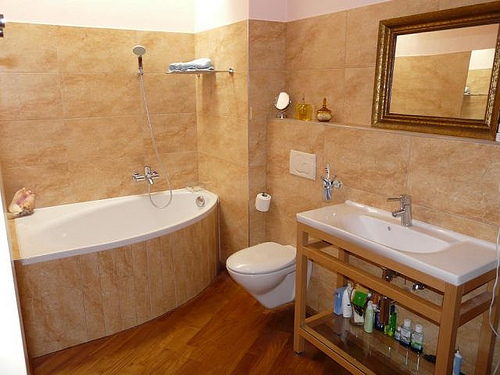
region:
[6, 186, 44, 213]
Shell on side of bathtub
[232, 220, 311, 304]
European style toilet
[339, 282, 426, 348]
Soaps and shampoos under sink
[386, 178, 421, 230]
Sink nossel is silver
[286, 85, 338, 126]
Oil in corner of bathroom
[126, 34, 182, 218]
Shower head over bath tub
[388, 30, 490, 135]
Mirror of bathroom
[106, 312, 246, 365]
Floor is wooden paneled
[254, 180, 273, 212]
Toilet paper roll on wall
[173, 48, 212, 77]
Blue folded towel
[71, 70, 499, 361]
Very clean bathroom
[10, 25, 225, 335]
A shower with no privacy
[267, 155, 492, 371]
No cabinet sink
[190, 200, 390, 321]
levatating toilet to sit on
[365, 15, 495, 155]
bathroom reflections in the mirror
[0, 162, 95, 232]
seashell soap dish holder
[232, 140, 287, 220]
Floating toilet tissue roll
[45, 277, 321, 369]
shiny clean wood flooring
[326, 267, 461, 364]
personal hygeine products to use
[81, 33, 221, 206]
removeable shower head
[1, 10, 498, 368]
a full bathroom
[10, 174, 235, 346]
a white bathtub with tile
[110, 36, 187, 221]
a hand held shower sprayer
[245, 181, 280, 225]
a roll of toilet paper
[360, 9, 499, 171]
a large mirror on the wall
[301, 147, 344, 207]
a toothbrush holder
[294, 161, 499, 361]
a bathroom sink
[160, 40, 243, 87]
a shelf with a towel on it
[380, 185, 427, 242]
a water faucet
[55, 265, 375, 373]
wood flooring in bathroom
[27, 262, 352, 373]
Hardwood floor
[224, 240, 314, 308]
White toilet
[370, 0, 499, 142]
Mirror on the wall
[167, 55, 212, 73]
Towel sitting on a rack above a tub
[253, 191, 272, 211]
Roll of toilet paper on the wall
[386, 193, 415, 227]
Silver faucet on a sink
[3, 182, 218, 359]
Bathtub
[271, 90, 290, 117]
Small round mirror on a silver stand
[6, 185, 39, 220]
Large seashell sitting on the side of a bathtub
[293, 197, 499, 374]
Wooden sink stand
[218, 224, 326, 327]
white toilet bowl hangs on wall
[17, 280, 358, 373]
floor made of hardwood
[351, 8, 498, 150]
mirror on wall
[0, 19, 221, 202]
tiles are light tan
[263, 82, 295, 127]
small mirror on shelf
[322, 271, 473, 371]
several items below sink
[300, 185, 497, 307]
sink is white and long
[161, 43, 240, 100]
white towel on shelf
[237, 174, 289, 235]
roll of toilet paper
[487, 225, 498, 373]
white power chord